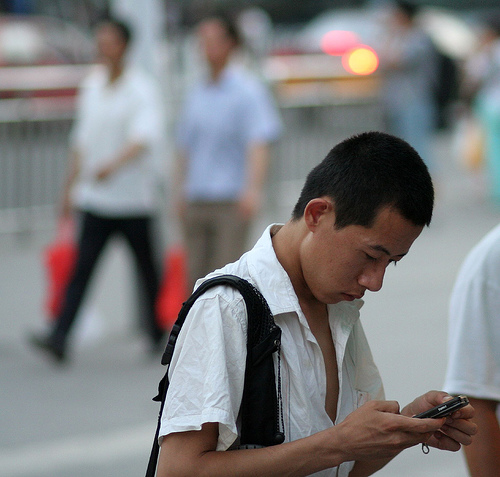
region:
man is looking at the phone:
[183, 148, 462, 449]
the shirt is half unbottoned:
[224, 240, 359, 447]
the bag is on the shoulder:
[148, 269, 321, 451]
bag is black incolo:
[180, 278, 285, 430]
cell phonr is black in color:
[370, 391, 495, 449]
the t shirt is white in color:
[448, 272, 497, 368]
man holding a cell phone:
[393, 354, 469, 456]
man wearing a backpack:
[136, 277, 282, 472]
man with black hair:
[300, 142, 430, 248]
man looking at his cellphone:
[288, 166, 495, 456]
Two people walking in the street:
[17, 4, 261, 389]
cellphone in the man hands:
[326, 359, 479, 457]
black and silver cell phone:
[384, 387, 476, 429]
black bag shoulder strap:
[123, 268, 300, 475]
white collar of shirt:
[229, 219, 311, 343]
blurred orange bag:
[34, 194, 81, 318]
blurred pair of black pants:
[31, 200, 168, 347]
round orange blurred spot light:
[329, 36, 391, 93]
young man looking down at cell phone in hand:
[131, 129, 476, 476]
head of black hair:
[286, 123, 441, 245]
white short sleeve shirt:
[152, 217, 391, 475]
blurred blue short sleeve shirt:
[168, 59, 287, 210]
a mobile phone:
[421, 400, 468, 412]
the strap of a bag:
[177, 277, 281, 349]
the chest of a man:
[301, 299, 339, 359]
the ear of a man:
[297, 187, 331, 232]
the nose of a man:
[363, 257, 385, 297]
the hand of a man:
[160, 426, 342, 475]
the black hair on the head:
[331, 120, 438, 217]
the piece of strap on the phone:
[416, 432, 432, 456]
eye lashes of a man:
[393, 258, 400, 265]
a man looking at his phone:
[181, 113, 436, 463]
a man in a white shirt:
[151, 128, 476, 475]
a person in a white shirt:
[443, 209, 498, 475]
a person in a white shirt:
[23, 13, 168, 370]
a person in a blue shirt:
[168, 10, 281, 300]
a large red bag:
[156, 223, 191, 325]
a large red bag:
[42, 215, 76, 311]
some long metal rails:
[1, 93, 390, 245]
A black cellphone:
[406, 391, 472, 422]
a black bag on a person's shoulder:
[141, 272, 286, 475]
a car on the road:
[270, 11, 457, 128]